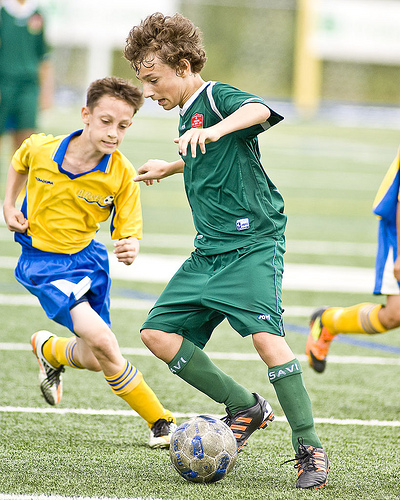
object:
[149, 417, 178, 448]
cleats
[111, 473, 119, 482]
grass blade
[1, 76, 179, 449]
boy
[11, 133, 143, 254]
jersey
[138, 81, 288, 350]
soccer uniform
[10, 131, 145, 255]
soccer uniform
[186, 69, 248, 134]
wall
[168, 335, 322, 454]
green socks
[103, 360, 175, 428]
sock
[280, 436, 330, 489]
cleat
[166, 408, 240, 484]
fence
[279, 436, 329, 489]
shoe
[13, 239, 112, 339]
shorts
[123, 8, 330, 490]
boy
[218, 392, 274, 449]
shoe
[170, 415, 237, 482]
ball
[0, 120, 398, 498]
ground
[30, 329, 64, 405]
cleats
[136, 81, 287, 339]
uniform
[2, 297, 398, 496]
grass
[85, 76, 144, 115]
boy's hair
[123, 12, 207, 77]
boy's hair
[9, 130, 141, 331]
uniform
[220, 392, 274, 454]
cleats